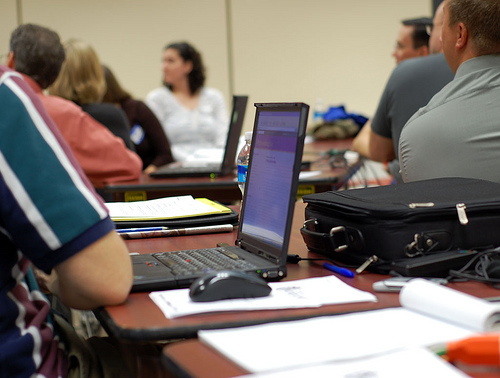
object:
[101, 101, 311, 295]
computer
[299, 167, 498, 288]
bag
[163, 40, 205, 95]
hair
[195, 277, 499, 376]
note pad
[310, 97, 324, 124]
bottle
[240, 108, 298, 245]
screen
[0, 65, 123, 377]
shirt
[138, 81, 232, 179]
shirt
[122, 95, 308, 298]
laptop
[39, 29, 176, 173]
woman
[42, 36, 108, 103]
hair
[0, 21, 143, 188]
man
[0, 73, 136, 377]
man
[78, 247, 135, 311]
elbow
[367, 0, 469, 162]
man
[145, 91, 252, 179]
laptop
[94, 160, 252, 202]
table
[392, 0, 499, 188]
person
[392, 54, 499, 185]
shirt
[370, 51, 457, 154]
shirt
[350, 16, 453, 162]
person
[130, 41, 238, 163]
woman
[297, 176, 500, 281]
case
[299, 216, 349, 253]
handle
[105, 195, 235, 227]
paper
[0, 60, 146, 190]
shirt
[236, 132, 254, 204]
bottle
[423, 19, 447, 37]
glasses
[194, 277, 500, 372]
paper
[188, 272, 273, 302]
computer mouse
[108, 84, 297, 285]
laptop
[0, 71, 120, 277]
shirt sleeve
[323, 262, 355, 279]
ink pen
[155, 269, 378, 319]
paper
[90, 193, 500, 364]
desk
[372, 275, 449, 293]
cell phone